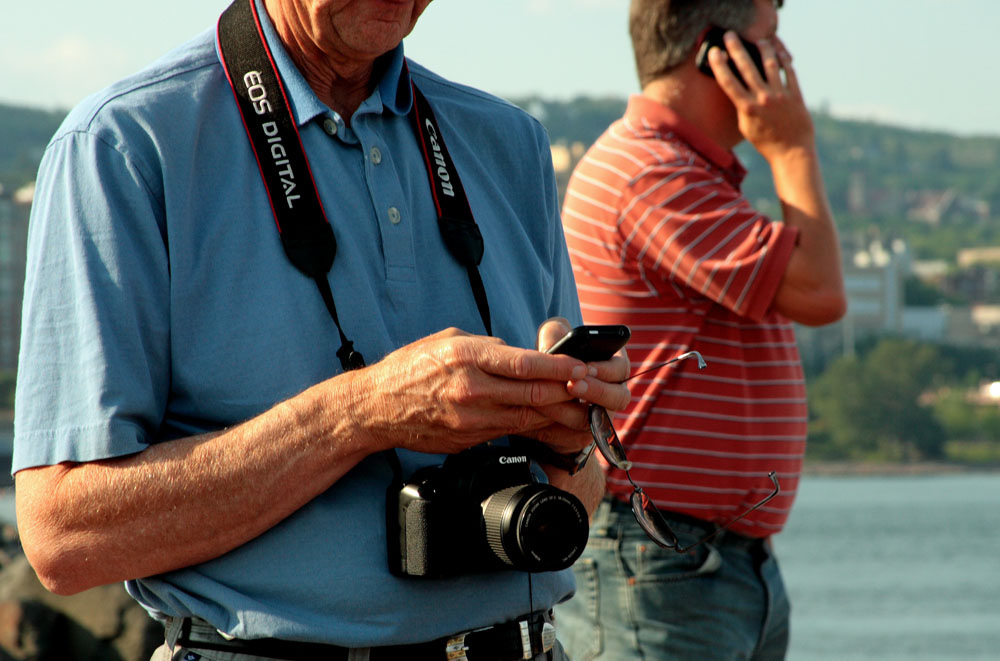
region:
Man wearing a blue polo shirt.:
[10, 3, 614, 657]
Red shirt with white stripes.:
[558, 91, 806, 539]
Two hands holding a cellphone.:
[380, 313, 640, 461]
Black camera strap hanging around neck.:
[205, 3, 496, 371]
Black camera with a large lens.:
[382, 439, 589, 594]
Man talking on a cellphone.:
[548, 3, 852, 658]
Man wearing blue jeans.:
[544, 4, 851, 656]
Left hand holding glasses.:
[542, 314, 786, 562]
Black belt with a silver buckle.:
[154, 607, 561, 658]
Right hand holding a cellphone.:
[691, 23, 816, 154]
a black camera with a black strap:
[211, 0, 589, 581]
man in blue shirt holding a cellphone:
[12, 0, 629, 658]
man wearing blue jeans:
[544, 0, 845, 657]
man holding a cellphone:
[562, 0, 846, 657]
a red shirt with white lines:
[555, 98, 803, 540]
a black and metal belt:
[158, 605, 559, 656]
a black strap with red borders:
[214, 0, 499, 337]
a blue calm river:
[771, 475, 995, 657]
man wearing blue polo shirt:
[12, 3, 637, 658]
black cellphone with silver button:
[546, 324, 633, 364]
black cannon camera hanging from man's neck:
[381, 433, 596, 585]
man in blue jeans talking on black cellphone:
[546, 4, 843, 658]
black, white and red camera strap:
[213, 0, 495, 462]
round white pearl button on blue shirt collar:
[363, 143, 384, 167]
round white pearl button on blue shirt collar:
[385, 206, 406, 224]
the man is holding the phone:
[340, 258, 667, 466]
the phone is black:
[521, 295, 651, 386]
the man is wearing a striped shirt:
[545, 0, 856, 565]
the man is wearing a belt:
[102, 604, 570, 654]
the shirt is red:
[541, 81, 821, 548]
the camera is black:
[338, 425, 616, 597]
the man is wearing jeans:
[544, 252, 809, 650]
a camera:
[402, 453, 597, 585]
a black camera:
[389, 466, 586, 576]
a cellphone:
[535, 313, 632, 373]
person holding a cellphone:
[429, 317, 647, 454]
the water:
[835, 517, 957, 624]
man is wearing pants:
[602, 531, 722, 658]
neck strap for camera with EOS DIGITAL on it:
[215, 0, 523, 452]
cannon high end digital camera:
[387, 441, 591, 585]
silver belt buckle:
[435, 620, 553, 658]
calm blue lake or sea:
[772, 470, 997, 658]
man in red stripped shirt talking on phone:
[557, 0, 838, 658]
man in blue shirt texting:
[10, 0, 625, 656]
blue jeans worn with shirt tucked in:
[550, 507, 797, 658]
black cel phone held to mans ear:
[691, 14, 765, 114]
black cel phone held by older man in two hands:
[548, 318, 635, 375]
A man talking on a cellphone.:
[566, 3, 836, 650]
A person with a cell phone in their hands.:
[26, 17, 648, 657]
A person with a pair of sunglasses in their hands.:
[24, 3, 619, 657]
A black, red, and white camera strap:
[196, 17, 516, 391]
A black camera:
[392, 441, 603, 586]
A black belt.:
[149, 604, 583, 655]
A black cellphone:
[552, 313, 642, 370]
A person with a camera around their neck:
[19, 4, 653, 658]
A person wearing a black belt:
[28, 7, 636, 657]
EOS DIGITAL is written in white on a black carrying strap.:
[220, 61, 315, 213]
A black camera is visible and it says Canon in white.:
[367, 431, 602, 598]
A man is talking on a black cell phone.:
[563, 0, 868, 655]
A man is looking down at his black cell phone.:
[16, 3, 643, 658]